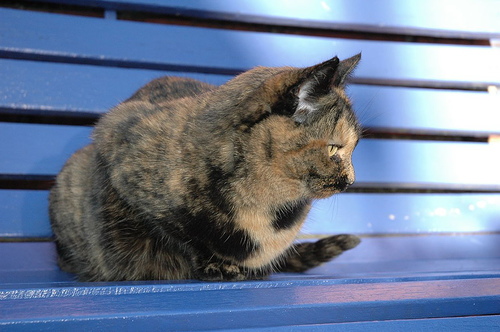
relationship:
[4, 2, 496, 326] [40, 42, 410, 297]
bench supporting a cat